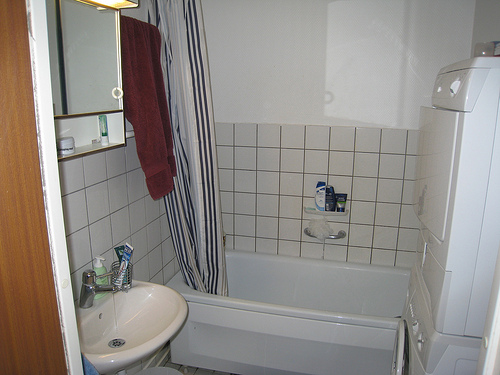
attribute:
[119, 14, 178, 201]
towel — hanging, burgundy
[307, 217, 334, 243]
loofa — white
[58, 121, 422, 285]
tiles — white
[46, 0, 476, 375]
walls — tiled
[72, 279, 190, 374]
sink — white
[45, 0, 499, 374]
bathroom — white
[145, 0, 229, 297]
shower curtain — striped, black, white